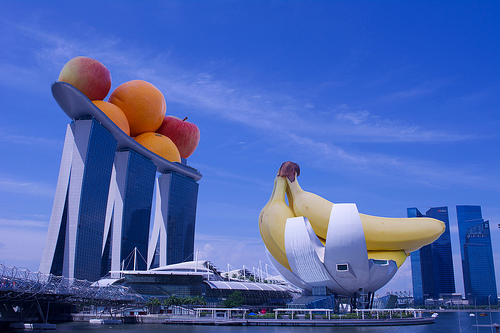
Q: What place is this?
A: It is a city.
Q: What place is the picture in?
A: It is at the city.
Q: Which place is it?
A: It is a city.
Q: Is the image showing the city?
A: Yes, it is showing the city.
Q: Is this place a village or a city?
A: It is a city.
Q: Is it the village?
A: No, it is the city.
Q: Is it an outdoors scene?
A: Yes, it is outdoors.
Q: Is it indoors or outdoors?
A: It is outdoors.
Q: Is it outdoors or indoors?
A: It is outdoors.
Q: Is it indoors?
A: No, it is outdoors.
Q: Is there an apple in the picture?
A: Yes, there is an apple.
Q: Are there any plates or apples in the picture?
A: Yes, there is an apple.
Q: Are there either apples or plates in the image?
A: Yes, there is an apple.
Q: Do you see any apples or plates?
A: Yes, there is an apple.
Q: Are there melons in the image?
A: No, there are no melons.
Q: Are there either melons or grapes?
A: No, there are no melons or grapes.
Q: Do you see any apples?
A: Yes, there is an apple.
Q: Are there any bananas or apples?
A: Yes, there is an apple.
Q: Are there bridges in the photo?
A: Yes, there is a bridge.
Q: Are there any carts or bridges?
A: Yes, there is a bridge.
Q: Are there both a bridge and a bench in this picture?
A: No, there is a bridge but no benches.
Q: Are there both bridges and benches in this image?
A: No, there is a bridge but no benches.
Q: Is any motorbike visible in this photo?
A: No, there are no motorcycles.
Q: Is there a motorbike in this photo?
A: No, there are no motorcycles.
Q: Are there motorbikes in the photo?
A: No, there are no motorbikes.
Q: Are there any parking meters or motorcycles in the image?
A: No, there are no motorcycles or parking meters.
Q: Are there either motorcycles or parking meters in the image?
A: No, there are no motorcycles or parking meters.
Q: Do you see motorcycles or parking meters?
A: No, there are no motorcycles or parking meters.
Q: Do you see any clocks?
A: No, there are no clocks.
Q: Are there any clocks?
A: No, there are no clocks.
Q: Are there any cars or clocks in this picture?
A: No, there are no clocks or cars.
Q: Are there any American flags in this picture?
A: No, there are no American flags.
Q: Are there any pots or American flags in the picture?
A: No, there are no American flags or pots.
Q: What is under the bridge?
A: The dock is under the bridge.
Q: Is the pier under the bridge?
A: Yes, the pier is under the bridge.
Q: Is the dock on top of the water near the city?
A: Yes, the dock is on top of the water.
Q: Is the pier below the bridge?
A: Yes, the pier is below the bridge.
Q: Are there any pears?
A: No, there are no pears.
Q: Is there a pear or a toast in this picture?
A: No, there are no pears or toasts.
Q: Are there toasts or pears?
A: No, there are no pears or toasts.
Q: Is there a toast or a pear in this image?
A: No, there are no pears or toasts.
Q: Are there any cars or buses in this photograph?
A: No, there are no cars or buses.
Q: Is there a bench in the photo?
A: No, there are no benches.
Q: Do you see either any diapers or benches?
A: No, there are no benches or diapers.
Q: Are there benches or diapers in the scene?
A: No, there are no benches or diapers.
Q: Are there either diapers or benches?
A: No, there are no benches or diapers.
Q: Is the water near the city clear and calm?
A: Yes, the water is clear and calm.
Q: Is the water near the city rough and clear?
A: No, the water is clear but calm.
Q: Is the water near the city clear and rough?
A: No, the water is clear but calm.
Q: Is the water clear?
A: Yes, the water is clear.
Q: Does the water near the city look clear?
A: Yes, the water is clear.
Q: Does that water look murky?
A: No, the water is clear.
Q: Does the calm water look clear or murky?
A: The water is clear.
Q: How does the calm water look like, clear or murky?
A: The water is clear.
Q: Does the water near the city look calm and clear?
A: Yes, the water is calm and clear.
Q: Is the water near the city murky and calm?
A: No, the water is calm but clear.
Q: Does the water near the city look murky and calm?
A: No, the water is calm but clear.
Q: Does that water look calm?
A: Yes, the water is calm.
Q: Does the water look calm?
A: Yes, the water is calm.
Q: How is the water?
A: The water is calm.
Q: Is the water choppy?
A: No, the water is calm.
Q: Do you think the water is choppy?
A: No, the water is calm.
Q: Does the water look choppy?
A: No, the water is calm.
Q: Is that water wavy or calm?
A: The water is calm.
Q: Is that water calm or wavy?
A: The water is calm.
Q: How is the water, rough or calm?
A: The water is calm.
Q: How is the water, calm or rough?
A: The water is calm.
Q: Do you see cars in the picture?
A: No, there are no cars.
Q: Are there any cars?
A: No, there are no cars.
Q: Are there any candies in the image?
A: No, there are no candies.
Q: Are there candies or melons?
A: No, there are no candies or melons.